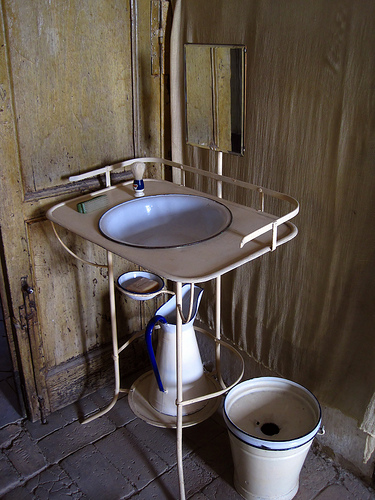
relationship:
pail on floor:
[221, 375, 325, 499] [0, 363, 374, 499]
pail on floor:
[187, 377, 364, 482] [24, 393, 126, 482]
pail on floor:
[221, 375, 325, 499] [56, 422, 191, 490]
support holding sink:
[79, 397, 120, 427] [96, 191, 248, 253]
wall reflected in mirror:
[184, 46, 229, 150] [183, 40, 248, 156]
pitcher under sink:
[146, 282, 212, 416] [99, 193, 229, 247]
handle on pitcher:
[128, 297, 184, 390] [106, 268, 235, 482]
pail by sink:
[221, 375, 325, 499] [37, 160, 302, 434]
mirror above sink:
[181, 43, 245, 154] [99, 193, 229, 247]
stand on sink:
[47, 154, 309, 499] [99, 193, 229, 247]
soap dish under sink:
[118, 269, 166, 301] [40, 153, 306, 290]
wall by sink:
[2, 0, 175, 431] [40, 153, 306, 290]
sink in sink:
[98, 191, 234, 245] [40, 153, 306, 290]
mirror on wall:
[181, 43, 245, 154] [187, 1, 371, 378]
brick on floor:
[0, 448, 23, 495] [0, 383, 375, 499]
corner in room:
[158, 6, 196, 324] [0, 1, 368, 496]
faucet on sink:
[131, 162, 144, 196] [98, 197, 234, 251]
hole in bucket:
[259, 422, 278, 436] [220, 376, 326, 498]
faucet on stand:
[130, 162, 145, 198] [47, 154, 309, 499]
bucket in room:
[220, 376, 326, 498] [0, 1, 375, 500]